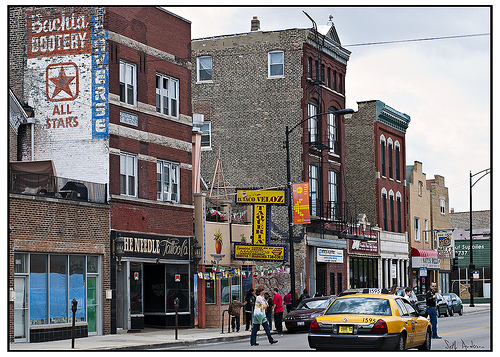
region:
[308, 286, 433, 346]
Yellow taxicab on the street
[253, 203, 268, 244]
Store sign advertising a taqueria restaurant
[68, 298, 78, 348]
Coin-operated parking meter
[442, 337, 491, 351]
Signature on the bottom-right corner of photo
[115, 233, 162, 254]
Shop sign saying "The Needle"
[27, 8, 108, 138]
Sign painted on side of building advertising Converse All Stars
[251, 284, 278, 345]
Woman walking on the street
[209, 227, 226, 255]
Pineapple painted on front of building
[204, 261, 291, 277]
Several Mexican flags strung in front of restaurant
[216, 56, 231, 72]
gray brick on building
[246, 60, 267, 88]
gray brick on building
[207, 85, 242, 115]
gray brick on building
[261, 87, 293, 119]
gray brick on building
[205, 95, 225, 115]
gray brick on building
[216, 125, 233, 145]
gray brick on building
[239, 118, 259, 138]
gray brick on building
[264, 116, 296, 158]
gray brick on building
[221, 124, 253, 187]
gray brick on building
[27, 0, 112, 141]
red and white sign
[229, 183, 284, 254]
yellow and red sign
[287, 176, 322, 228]
yellow and orange banner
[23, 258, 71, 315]
blue tarp on windows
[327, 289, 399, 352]
black and yellow taxi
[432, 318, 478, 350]
yellow line on road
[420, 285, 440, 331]
man walking on road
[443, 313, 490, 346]
road is light grey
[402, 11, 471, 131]
grey and white sky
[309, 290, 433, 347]
a yellow taxi cab numbered 1595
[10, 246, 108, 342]
street front windows of an abandonded store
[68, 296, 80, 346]
a parking meter with a black head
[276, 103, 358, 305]
red and yellow sign on a black street lamp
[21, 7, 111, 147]
fading sign for converse shoes on a brick wall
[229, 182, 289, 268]
yellow sign for a taco shop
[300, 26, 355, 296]
metal fire escape on brick building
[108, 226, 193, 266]
sign advertising a tatoo parlor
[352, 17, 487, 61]
telephone wire hanging in the air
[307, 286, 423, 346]
a yellow taxi cab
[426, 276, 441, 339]
a man standing in a street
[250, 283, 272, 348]
a woman walking in the street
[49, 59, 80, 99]
a red star on a wall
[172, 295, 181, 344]
a parking meter on a side walk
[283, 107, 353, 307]
a black street light pole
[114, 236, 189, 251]
a sign over a store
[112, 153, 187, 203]
windows over a store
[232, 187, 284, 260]
a yellow and red sign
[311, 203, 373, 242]
a fire escape ladder